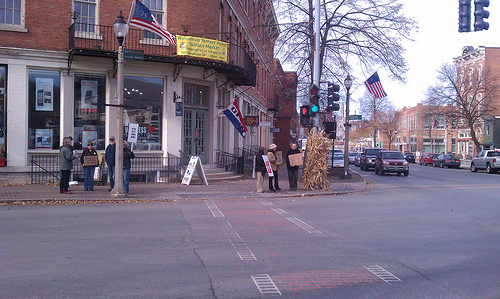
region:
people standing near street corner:
[3, 20, 473, 291]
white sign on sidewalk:
[165, 140, 221, 207]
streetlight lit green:
[284, 65, 350, 130]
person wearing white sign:
[252, 133, 281, 190]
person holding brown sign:
[286, 137, 308, 179]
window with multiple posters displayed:
[10, 43, 189, 164]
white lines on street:
[182, 178, 424, 298]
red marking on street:
[205, 159, 404, 297]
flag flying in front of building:
[87, 0, 196, 80]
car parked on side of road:
[342, 25, 498, 213]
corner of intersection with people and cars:
[5, 6, 486, 284]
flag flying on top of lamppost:
[110, 0, 175, 195]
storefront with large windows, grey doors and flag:
[5, 65, 270, 180]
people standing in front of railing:
[30, 130, 177, 180]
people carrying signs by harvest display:
[246, 125, 331, 195]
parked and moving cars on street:
[326, 142, 496, 182]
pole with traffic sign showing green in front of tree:
[285, 5, 405, 131]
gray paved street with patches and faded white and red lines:
[2, 151, 492, 292]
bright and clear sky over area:
[275, 0, 496, 115]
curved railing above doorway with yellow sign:
[5, 5, 280, 86]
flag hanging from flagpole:
[351, 67, 386, 99]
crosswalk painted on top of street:
[207, 195, 404, 297]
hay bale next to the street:
[300, 133, 328, 188]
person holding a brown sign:
[283, 142, 307, 190]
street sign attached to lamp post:
[346, 113, 361, 120]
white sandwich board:
[178, 154, 208, 185]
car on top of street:
[373, 148, 409, 177]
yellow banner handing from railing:
[173, 33, 228, 60]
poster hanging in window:
[34, 77, 54, 111]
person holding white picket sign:
[121, 123, 143, 194]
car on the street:
[371, 147, 414, 177]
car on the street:
[357, 143, 386, 173]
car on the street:
[428, 149, 465, 171]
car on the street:
[466, 143, 498, 175]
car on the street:
[419, 149, 439, 166]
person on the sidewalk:
[52, 130, 84, 197]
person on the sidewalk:
[75, 136, 100, 193]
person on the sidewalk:
[102, 131, 118, 196]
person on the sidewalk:
[249, 143, 269, 197]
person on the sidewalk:
[283, 138, 308, 192]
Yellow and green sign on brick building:
[175, 33, 227, 61]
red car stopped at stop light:
[374, 148, 407, 175]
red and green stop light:
[301, 82, 340, 129]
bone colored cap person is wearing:
[267, 142, 277, 149]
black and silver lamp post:
[106, 12, 128, 198]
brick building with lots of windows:
[1, 3, 271, 113]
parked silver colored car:
[470, 147, 498, 172]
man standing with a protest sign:
[79, 140, 99, 192]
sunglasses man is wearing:
[104, 138, 118, 142]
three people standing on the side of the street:
[255, 144, 304, 192]